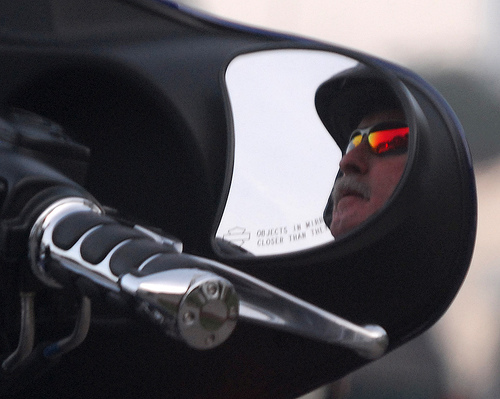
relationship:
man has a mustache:
[326, 107, 414, 243] [326, 172, 374, 212]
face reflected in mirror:
[327, 108, 415, 234] [209, 37, 431, 269]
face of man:
[327, 108, 415, 234] [326, 107, 414, 243]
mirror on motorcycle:
[214, 45, 416, 275] [1, 1, 478, 395]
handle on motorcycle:
[26, 195, 238, 347] [1, 1, 478, 395]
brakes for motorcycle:
[183, 268, 400, 354] [1, 1, 478, 395]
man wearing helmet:
[326, 107, 414, 243] [315, 63, 408, 154]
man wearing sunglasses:
[322, 106, 410, 238] [329, 119, 411, 163]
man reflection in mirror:
[326, 107, 414, 243] [209, 37, 431, 269]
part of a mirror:
[291, 108, 386, 186] [204, 45, 421, 260]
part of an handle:
[55, 212, 136, 278] [56, 209, 267, 354]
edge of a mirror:
[306, 216, 349, 251] [333, 187, 358, 215]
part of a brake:
[127, 246, 161, 316] [145, 250, 383, 358]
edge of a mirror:
[209, 46, 419, 264] [204, 45, 421, 260]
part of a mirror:
[243, 171, 276, 208] [230, 60, 394, 251]